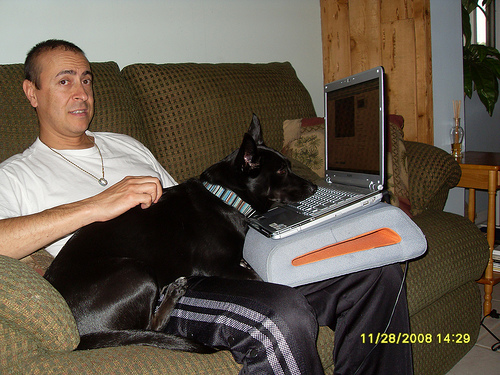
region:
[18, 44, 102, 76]
man has short hair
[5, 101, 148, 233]
man has white shirt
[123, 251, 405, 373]
grey and white pants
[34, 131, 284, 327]
man is holding dog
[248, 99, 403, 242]
grey laptop on pillow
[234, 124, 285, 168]
dog has black ears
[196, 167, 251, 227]
dog has striped collar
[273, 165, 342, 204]
grey keyboard on laptop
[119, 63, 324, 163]
brown cushions on sofa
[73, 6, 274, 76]
white wall behind man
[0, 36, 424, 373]
Man sitting on sofa with dog and laptop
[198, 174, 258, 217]
Striped collar around dog's neck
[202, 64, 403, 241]
Dog looking at the laptop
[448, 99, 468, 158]
Candle on the table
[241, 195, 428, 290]
Lap pad under the laptop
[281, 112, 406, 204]
Pillow on the sofa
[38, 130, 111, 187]
Chain around man's neck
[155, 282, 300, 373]
Two stripes on side of man's pants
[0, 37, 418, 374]
Dog sitting on man's lap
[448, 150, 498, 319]
Small wooden table against the wall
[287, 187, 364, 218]
key's on the keyboard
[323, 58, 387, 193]
screen of the laptop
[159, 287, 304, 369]
stripes on the man's pants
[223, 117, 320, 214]
head of the dog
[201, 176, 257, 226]
collar on the dog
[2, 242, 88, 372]
pillow on the couch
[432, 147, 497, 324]
table next to the couch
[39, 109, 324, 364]
dog on the man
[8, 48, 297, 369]
man with the dog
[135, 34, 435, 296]
Lap top on the man's lap.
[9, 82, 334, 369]
Dog on the couch.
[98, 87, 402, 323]
Collar on the dog.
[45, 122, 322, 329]
Dark dog on the couch.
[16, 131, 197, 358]
Black dog on the couch.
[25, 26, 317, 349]
Man on the couch.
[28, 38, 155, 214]
Man with a necklace.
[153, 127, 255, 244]
Striped collar on the dog.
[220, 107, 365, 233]
Keys on the keyboard.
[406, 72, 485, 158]
Item on the table.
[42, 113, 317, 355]
a shiny black dog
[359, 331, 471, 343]
a yellow date and time stamp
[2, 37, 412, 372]
a man wearing a white t-shirt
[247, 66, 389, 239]
a silver colored laptop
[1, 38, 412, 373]
a man sitting with a dog across one leg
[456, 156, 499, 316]
a brown wooden table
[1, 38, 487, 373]
the man sitting on a couch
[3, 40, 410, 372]
a man with short hair and a necklace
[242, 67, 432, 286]
a laptop on a cushioned stand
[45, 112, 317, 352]
the dog has a multicolored collar